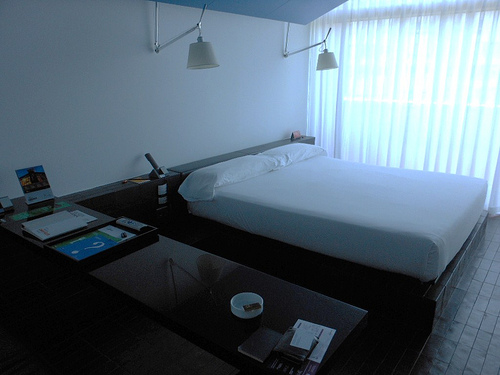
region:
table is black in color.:
[143, 251, 209, 306]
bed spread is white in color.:
[307, 178, 408, 222]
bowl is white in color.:
[230, 288, 273, 319]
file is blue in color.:
[67, 237, 120, 260]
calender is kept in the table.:
[13, 154, 72, 215]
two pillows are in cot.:
[197, 146, 337, 184]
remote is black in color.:
[145, 148, 175, 184]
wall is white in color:
[55, 123, 108, 164]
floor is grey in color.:
[451, 305, 491, 374]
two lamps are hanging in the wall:
[166, 15, 357, 81]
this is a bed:
[190, 138, 499, 256]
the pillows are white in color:
[197, 142, 314, 191]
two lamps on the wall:
[180, 44, 343, 79]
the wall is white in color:
[28, 72, 195, 146]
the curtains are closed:
[338, 15, 484, 158]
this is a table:
[112, 262, 304, 372]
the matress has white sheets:
[235, 171, 482, 249]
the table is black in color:
[123, 251, 218, 301]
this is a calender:
[15, 160, 55, 205]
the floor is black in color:
[460, 293, 495, 342]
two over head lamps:
[143, 1, 350, 84]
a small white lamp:
[177, 24, 235, 84]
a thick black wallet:
[268, 320, 335, 369]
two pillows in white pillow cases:
[176, 138, 323, 193]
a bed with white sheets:
[192, 121, 499, 286]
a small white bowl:
[218, 285, 265, 322]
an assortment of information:
[6, 160, 162, 275]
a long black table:
[26, 176, 396, 371]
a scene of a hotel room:
[6, 102, 490, 372]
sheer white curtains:
[311, 20, 496, 190]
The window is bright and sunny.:
[307, 0, 499, 219]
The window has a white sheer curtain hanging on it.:
[305, 0, 499, 220]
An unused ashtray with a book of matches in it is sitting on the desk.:
[227, 288, 266, 320]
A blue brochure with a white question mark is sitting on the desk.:
[59, 235, 107, 257]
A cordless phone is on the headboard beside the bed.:
[143, 153, 168, 180]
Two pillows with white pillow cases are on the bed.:
[174, 140, 328, 202]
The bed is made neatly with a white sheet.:
[180, 156, 487, 282]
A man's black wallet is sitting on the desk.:
[269, 320, 319, 365]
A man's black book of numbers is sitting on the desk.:
[234, 324, 285, 365]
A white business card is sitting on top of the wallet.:
[286, 324, 317, 351]